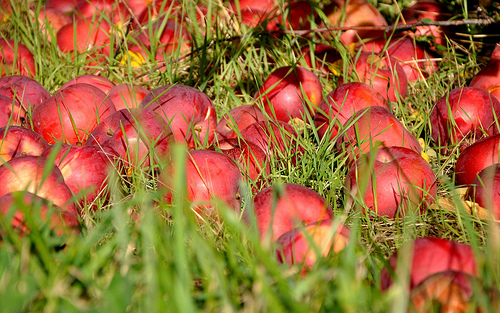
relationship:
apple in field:
[345, 143, 437, 218] [2, 49, 483, 309]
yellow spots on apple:
[305, 221, 344, 260] [277, 217, 357, 272]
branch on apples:
[115, 8, 495, 90] [8, 6, 498, 104]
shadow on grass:
[194, 29, 278, 94] [151, 25, 329, 120]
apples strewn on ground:
[4, 3, 498, 302] [1, 3, 497, 311]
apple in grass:
[50, 143, 130, 213] [3, 11, 498, 311]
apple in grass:
[4, 146, 73, 232] [3, 11, 498, 311]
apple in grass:
[136, 78, 236, 161] [3, 11, 498, 311]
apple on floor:
[345, 143, 437, 218] [160, 194, 250, 303]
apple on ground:
[240, 159, 309, 246] [119, 211, 198, 280]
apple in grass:
[38, 78, 110, 144] [112, 217, 187, 271]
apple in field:
[378, 238, 483, 295] [62, 26, 448, 289]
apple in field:
[380, 209, 470, 301] [82, 22, 467, 299]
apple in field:
[183, 110, 289, 209] [66, 20, 420, 269]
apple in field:
[136, 82, 217, 146] [21, 18, 427, 281]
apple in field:
[159, 149, 243, 226] [41, 37, 449, 304]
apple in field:
[355, 35, 465, 143] [78, 36, 450, 276]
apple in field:
[43, 15, 124, 81] [21, 18, 427, 281]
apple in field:
[244, 46, 326, 126] [82, 22, 467, 299]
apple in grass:
[88, 111, 177, 182] [41, 15, 415, 291]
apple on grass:
[345, 129, 429, 214] [109, 211, 214, 306]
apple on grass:
[150, 135, 255, 251] [99, 212, 229, 292]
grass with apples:
[102, 214, 196, 284] [58, 21, 432, 277]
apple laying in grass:
[426, 86, 498, 157] [3, 11, 498, 311]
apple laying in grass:
[273, 215, 358, 270] [3, 11, 498, 311]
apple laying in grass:
[159, 149, 240, 216] [3, 11, 498, 311]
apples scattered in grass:
[4, 3, 498, 302] [3, 11, 498, 311]